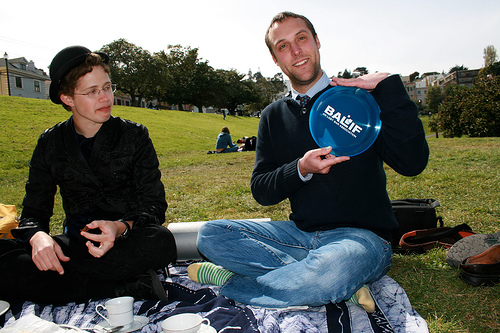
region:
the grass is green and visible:
[131, 84, 361, 291]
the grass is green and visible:
[311, 151, 445, 330]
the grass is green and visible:
[345, 132, 496, 233]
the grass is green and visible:
[338, 85, 495, 317]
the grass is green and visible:
[436, 76, 491, 198]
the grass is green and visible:
[413, 156, 490, 273]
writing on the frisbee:
[320, 105, 363, 140]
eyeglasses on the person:
[85, 84, 115, 95]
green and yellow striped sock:
[192, 265, 224, 282]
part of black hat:
[50, 48, 96, 65]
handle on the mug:
[93, 303, 112, 319]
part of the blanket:
[250, 316, 321, 331]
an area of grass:
[446, 165, 488, 201]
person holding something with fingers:
[81, 221, 94, 238]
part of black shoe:
[455, 257, 499, 283]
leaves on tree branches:
[125, 52, 194, 82]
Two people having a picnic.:
[10, 12, 448, 307]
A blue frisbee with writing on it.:
[305, 80, 380, 165]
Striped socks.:
[180, 255, 230, 290]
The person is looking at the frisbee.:
[25, 45, 395, 200]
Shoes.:
[427, 212, 494, 287]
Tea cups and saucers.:
[87, 295, 227, 330]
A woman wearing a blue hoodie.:
[210, 120, 235, 155]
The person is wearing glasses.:
[65, 75, 120, 107]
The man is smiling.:
[252, 1, 334, 106]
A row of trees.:
[105, 36, 276, 124]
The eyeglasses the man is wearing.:
[79, 80, 117, 97]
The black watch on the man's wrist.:
[111, 215, 133, 235]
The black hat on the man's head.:
[40, 49, 119, 94]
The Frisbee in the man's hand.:
[303, 80, 391, 156]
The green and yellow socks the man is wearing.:
[186, 254, 386, 321]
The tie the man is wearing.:
[287, 87, 312, 117]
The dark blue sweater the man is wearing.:
[238, 76, 418, 239]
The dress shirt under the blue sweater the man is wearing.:
[279, 78, 339, 103]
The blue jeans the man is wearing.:
[200, 202, 392, 326]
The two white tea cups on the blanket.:
[90, 290, 229, 330]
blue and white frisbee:
[310, 83, 382, 153]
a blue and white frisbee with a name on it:
[304, 82, 388, 159]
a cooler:
[396, 192, 449, 230]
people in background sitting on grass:
[196, 126, 259, 154]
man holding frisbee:
[190, 20, 445, 314]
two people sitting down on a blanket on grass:
[0, 0, 433, 332]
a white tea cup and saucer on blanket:
[148, 312, 218, 330]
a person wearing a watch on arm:
[61, 212, 133, 259]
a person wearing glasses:
[72, 79, 120, 101]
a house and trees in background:
[0, 29, 498, 134]